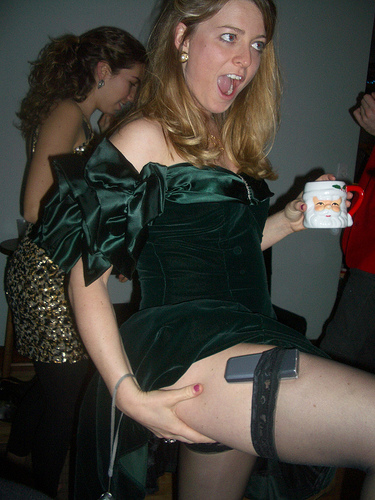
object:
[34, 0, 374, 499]
woman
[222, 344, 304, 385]
telephone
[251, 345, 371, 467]
stocking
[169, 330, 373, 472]
leg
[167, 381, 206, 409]
thumb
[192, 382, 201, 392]
nail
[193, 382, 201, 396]
polish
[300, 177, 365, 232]
mug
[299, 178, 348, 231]
santa claus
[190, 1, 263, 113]
face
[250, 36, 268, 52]
eyes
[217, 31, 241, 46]
eye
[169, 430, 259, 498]
leg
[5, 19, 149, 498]
girl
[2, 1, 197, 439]
background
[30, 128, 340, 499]
dress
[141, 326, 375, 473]
right leg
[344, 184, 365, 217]
handle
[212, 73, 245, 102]
mouth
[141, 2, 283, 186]
hair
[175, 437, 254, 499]
stocking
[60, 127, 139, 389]
arm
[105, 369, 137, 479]
strap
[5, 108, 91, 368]
dress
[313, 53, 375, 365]
man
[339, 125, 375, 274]
sweatshirt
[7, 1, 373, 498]
scene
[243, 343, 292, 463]
top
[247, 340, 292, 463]
garter band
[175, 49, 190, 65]
earring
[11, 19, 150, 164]
hair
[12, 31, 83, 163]
pony tail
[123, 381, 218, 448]
hand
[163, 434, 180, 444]
ring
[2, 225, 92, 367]
skirt